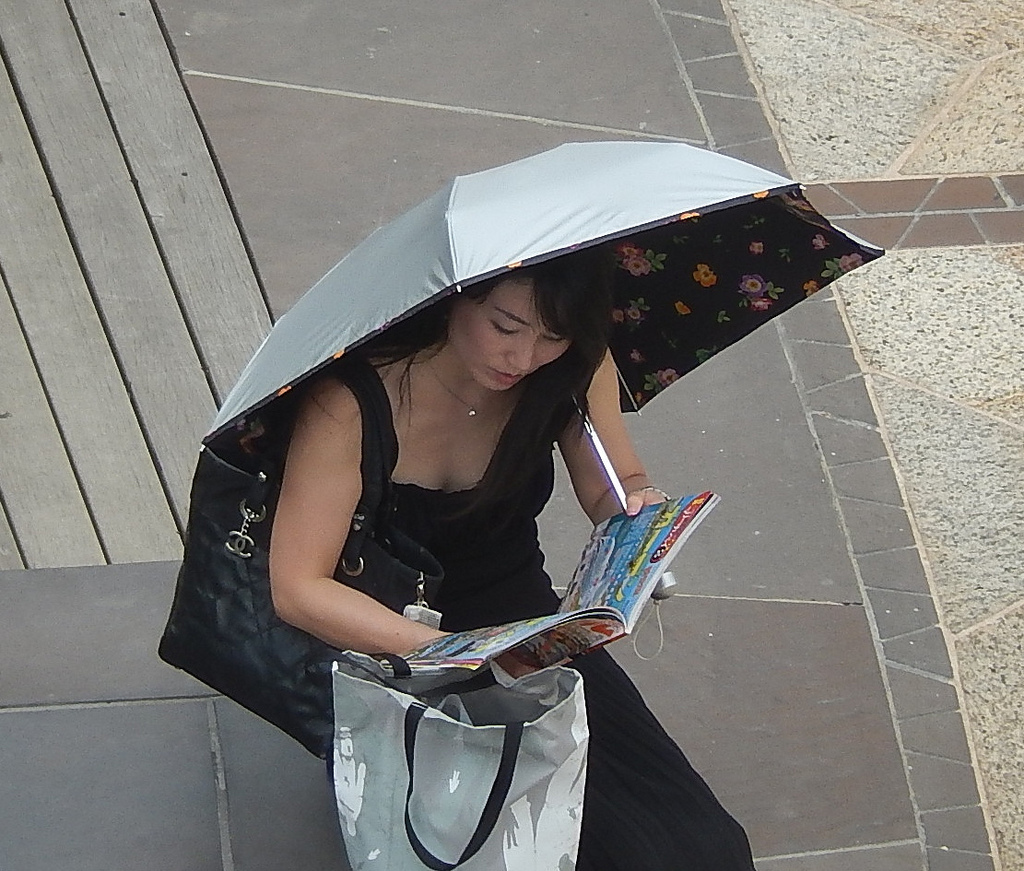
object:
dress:
[329, 362, 751, 870]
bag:
[329, 649, 584, 870]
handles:
[402, 693, 522, 870]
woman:
[265, 251, 745, 871]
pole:
[573, 393, 679, 601]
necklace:
[427, 356, 477, 416]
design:
[607, 185, 883, 410]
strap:
[339, 356, 399, 494]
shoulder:
[285, 377, 362, 484]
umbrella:
[198, 138, 872, 603]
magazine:
[377, 490, 722, 671]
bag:
[158, 364, 449, 758]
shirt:
[339, 358, 564, 635]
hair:
[304, 243, 615, 452]